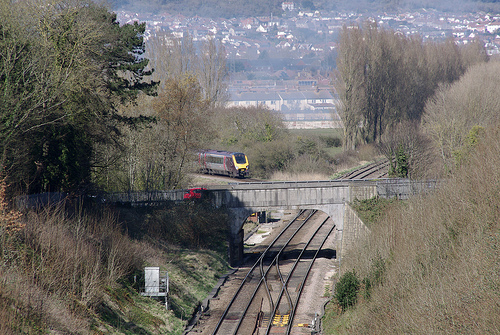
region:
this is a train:
[214, 150, 247, 175]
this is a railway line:
[242, 245, 292, 328]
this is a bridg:
[267, 182, 341, 203]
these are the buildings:
[233, 22, 325, 66]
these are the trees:
[15, 52, 177, 182]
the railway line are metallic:
[257, 278, 302, 333]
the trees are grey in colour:
[411, 210, 493, 313]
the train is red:
[187, 188, 204, 198]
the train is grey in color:
[206, 152, 227, 175]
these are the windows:
[202, 155, 224, 162]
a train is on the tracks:
[193, 145, 249, 182]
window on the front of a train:
[234, 152, 246, 163]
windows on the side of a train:
[190, 152, 221, 165]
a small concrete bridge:
[66, 175, 433, 264]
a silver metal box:
[143, 263, 161, 296]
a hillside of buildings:
[99, 3, 499, 121]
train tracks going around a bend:
[212, 136, 439, 334]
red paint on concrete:
[179, 184, 206, 202]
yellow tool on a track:
[267, 311, 290, 328]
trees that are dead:
[330, 22, 491, 162]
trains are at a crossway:
[205, 137, 360, 332]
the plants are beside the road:
[402, 206, 482, 334]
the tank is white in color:
[133, 255, 199, 334]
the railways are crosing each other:
[242, 233, 304, 320]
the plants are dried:
[391, 255, 439, 305]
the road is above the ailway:
[231, 175, 369, 223]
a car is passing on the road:
[184, 176, 228, 206]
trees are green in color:
[19, 48, 109, 151]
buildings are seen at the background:
[241, 25, 313, 90]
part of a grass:
[394, 241, 435, 306]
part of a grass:
[376, 221, 436, 279]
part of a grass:
[337, 230, 398, 289]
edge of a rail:
[303, 279, 317, 307]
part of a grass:
[362, 264, 398, 296]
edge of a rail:
[256, 269, 276, 313]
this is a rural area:
[35, 15, 461, 306]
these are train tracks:
[233, 230, 341, 311]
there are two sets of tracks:
[228, 254, 311, 316]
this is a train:
[190, 128, 272, 185]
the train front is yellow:
[217, 125, 253, 181]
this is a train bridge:
[145, 177, 326, 273]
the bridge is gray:
[234, 177, 365, 218]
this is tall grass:
[382, 169, 438, 323]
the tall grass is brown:
[386, 205, 493, 315]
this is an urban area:
[241, 5, 397, 107]